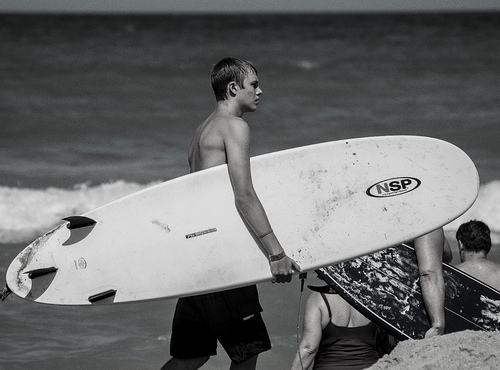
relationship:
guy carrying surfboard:
[194, 46, 271, 115] [24, 140, 447, 331]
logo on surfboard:
[362, 171, 422, 201] [24, 140, 447, 331]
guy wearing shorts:
[194, 46, 271, 115] [162, 273, 274, 363]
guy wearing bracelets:
[194, 46, 271, 115] [255, 229, 300, 273]